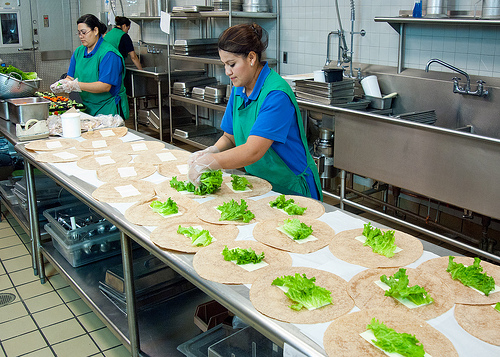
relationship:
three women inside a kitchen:
[50, 13, 323, 200] [1, 2, 497, 355]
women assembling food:
[50, 13, 323, 200] [21, 92, 499, 353]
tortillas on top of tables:
[21, 92, 499, 353] [1, 92, 499, 356]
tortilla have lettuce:
[192, 237, 295, 285] [148, 172, 499, 354]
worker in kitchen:
[187, 23, 324, 201] [1, 2, 497, 355]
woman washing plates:
[103, 16, 141, 73] [126, 60, 149, 71]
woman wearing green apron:
[103, 16, 141, 73] [102, 31, 127, 54]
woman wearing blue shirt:
[187, 23, 324, 201] [221, 61, 320, 199]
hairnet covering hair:
[217, 20, 270, 54] [217, 20, 268, 55]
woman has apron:
[187, 23, 324, 201] [232, 68, 322, 198]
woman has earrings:
[187, 23, 324, 201] [249, 60, 254, 67]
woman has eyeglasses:
[49, 14, 129, 126] [72, 28, 95, 35]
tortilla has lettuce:
[192, 237, 295, 285] [148, 172, 499, 354]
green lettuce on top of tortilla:
[148, 172, 499, 354] [192, 237, 295, 285]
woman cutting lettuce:
[187, 23, 324, 201] [148, 172, 499, 354]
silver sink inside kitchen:
[285, 59, 499, 220] [1, 2, 497, 355]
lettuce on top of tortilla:
[148, 172, 499, 354] [192, 237, 295, 285]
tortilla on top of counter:
[192, 237, 295, 285] [1, 92, 499, 356]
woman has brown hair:
[187, 23, 324, 201] [217, 20, 268, 55]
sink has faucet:
[285, 59, 499, 220] [424, 59, 490, 97]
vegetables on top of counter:
[1, 63, 88, 114] [1, 92, 499, 356]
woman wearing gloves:
[49, 14, 129, 126] [49, 75, 83, 95]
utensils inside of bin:
[52, 208, 125, 258] [44, 203, 141, 265]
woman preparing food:
[187, 23, 324, 201] [21, 92, 499, 353]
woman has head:
[103, 16, 141, 73] [115, 16, 131, 34]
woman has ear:
[49, 14, 129, 126] [92, 27, 100, 37]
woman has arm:
[49, 14, 129, 126] [59, 52, 122, 93]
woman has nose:
[49, 14, 129, 126] [76, 30, 85, 40]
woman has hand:
[49, 14, 129, 126] [59, 77, 84, 93]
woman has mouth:
[49, 14, 129, 126] [79, 38, 87, 44]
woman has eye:
[49, 14, 129, 126] [77, 28, 88, 38]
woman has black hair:
[103, 16, 141, 73] [116, 16, 132, 27]